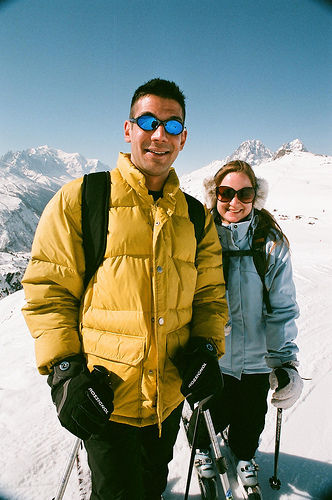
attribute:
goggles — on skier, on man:
[132, 115, 185, 135]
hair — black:
[137, 79, 184, 98]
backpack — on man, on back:
[83, 171, 113, 273]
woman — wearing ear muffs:
[255, 181, 268, 212]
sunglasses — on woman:
[216, 185, 256, 203]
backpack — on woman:
[249, 219, 275, 288]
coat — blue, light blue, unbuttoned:
[212, 217, 301, 370]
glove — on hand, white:
[269, 371, 308, 413]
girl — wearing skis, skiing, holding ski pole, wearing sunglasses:
[193, 157, 306, 499]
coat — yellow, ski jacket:
[22, 178, 231, 424]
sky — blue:
[4, 7, 331, 84]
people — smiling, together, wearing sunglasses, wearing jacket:
[23, 79, 227, 499]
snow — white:
[268, 154, 331, 232]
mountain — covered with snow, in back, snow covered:
[3, 148, 102, 180]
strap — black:
[180, 193, 209, 238]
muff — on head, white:
[200, 176, 217, 207]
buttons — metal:
[156, 259, 167, 331]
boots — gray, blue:
[195, 451, 259, 489]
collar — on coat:
[126, 172, 181, 203]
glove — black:
[56, 371, 118, 439]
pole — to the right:
[31, 362, 121, 498]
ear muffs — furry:
[204, 178, 214, 205]